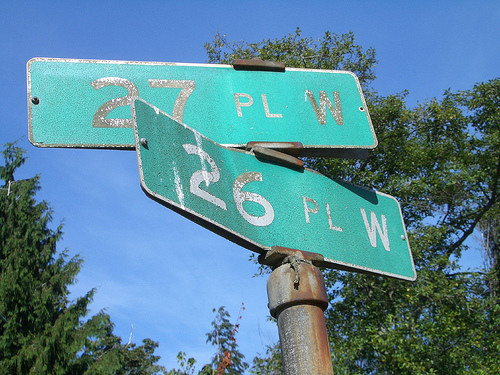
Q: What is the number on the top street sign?
A: 27.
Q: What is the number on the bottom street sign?
A: 26.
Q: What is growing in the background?
A: Trees.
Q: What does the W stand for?
A: West.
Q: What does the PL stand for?
A: Place.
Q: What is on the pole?
A: Street signs.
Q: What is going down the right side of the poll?
A: Rust.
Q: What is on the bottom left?
A: Tree.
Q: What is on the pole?
A: Street signs.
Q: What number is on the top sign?
A: 27.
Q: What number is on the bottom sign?
A: 26.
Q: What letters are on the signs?
A: PL W.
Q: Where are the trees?
A: Behind the sign.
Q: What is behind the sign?
A: Trees.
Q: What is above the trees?
A: The sky.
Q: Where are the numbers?
A: On the street signs.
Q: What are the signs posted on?
A: A metal pole.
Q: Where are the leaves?
A: On the trees.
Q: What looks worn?
A: Street sign.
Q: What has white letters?
A: Street sign.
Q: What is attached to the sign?
A: Rusted post.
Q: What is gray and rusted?
A: Metal pole.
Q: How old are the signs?
A: Very old.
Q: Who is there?
A: No one.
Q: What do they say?
A: Street names.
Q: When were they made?
A: Long ago.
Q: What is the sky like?
A: Clear.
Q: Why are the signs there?
A: Directions.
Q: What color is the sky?
A: Blue.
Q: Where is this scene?
A: Street corner.